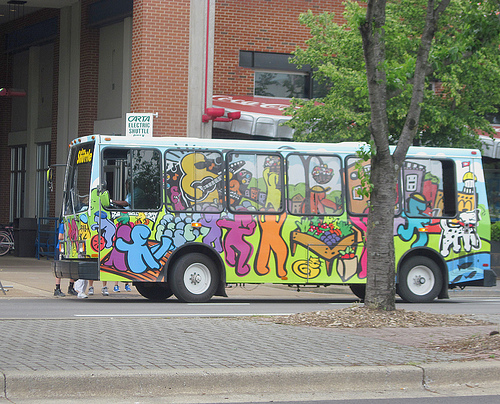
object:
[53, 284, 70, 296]
shoes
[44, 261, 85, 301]
person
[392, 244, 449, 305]
wheel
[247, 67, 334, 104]
window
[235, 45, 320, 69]
window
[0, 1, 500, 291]
building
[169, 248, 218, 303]
wheel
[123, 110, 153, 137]
sign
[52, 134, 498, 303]
bus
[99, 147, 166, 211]
window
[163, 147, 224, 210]
window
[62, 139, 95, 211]
window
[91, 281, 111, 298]
shoe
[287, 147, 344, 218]
window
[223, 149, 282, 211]
window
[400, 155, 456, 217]
window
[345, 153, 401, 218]
window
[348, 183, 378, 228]
wall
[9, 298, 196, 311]
black pavement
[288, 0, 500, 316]
tree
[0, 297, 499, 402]
road